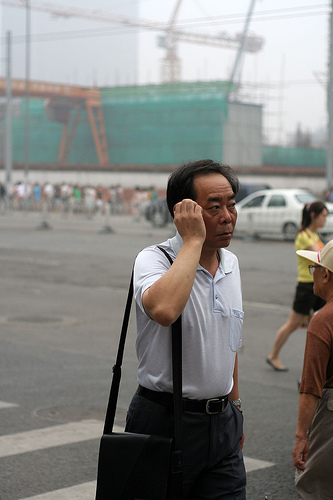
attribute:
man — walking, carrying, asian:
[121, 161, 245, 498]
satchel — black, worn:
[95, 245, 198, 499]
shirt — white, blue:
[133, 228, 245, 400]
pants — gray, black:
[124, 388, 246, 499]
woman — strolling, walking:
[263, 202, 331, 374]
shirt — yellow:
[295, 230, 328, 284]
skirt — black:
[290, 278, 332, 317]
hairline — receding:
[192, 173, 232, 181]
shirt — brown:
[298, 301, 332, 399]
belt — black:
[137, 385, 229, 414]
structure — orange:
[1, 77, 110, 165]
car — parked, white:
[231, 190, 332, 239]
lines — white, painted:
[4, 400, 273, 498]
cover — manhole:
[11, 315, 61, 325]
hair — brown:
[299, 199, 326, 232]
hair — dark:
[166, 159, 240, 216]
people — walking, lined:
[8, 182, 163, 215]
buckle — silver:
[207, 398, 222, 413]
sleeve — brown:
[299, 328, 327, 402]